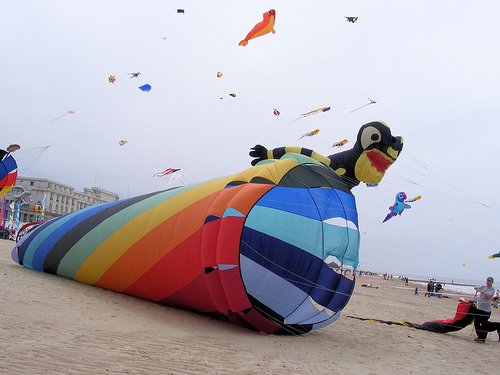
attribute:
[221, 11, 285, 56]
kite — flyer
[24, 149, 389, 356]
kite — multi colored, large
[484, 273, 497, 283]
hat —  grey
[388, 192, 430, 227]
kite — pink, blue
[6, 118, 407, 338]
kite — large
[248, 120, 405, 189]
kite — yellow, black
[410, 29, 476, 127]
sky — cloudy, grey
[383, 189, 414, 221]
kite — shaped 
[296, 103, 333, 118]
kites — flying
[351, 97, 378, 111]
kites — flying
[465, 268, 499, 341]
man —  wearing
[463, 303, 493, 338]
pants — black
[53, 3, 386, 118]
kites — many, flying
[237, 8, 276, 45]
kite — yellow, orange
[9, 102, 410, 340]
tunnel — multi colored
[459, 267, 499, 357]
man — looking